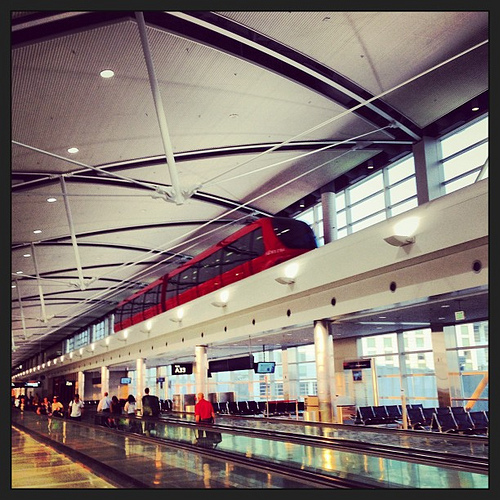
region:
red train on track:
[59, 173, 377, 368]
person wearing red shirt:
[189, 398, 215, 422]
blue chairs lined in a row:
[334, 378, 493, 454]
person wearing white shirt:
[67, 397, 87, 414]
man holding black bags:
[191, 420, 226, 451]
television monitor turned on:
[243, 351, 283, 385]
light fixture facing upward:
[257, 258, 309, 290]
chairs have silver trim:
[420, 400, 464, 445]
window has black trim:
[300, 91, 480, 226]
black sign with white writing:
[156, 356, 200, 379]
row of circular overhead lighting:
[36, 64, 116, 232]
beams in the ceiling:
[63, 86, 386, 191]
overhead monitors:
[246, 348, 292, 382]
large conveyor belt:
[181, 407, 412, 482]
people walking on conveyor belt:
[58, 375, 228, 432]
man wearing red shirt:
[185, 395, 220, 414]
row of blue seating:
[360, 389, 461, 429]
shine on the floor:
[255, 438, 377, 472]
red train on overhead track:
[102, 220, 328, 307]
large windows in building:
[217, 328, 457, 426]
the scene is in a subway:
[63, 35, 488, 488]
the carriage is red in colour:
[81, 186, 356, 286]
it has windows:
[101, 271, 240, 301]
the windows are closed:
[132, 260, 229, 296]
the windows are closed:
[333, 148, 444, 228]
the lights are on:
[48, 138, 92, 155]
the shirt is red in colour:
[179, 390, 216, 421]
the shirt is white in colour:
[121, 398, 141, 410]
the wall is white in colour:
[315, 235, 351, 285]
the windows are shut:
[363, 342, 427, 406]